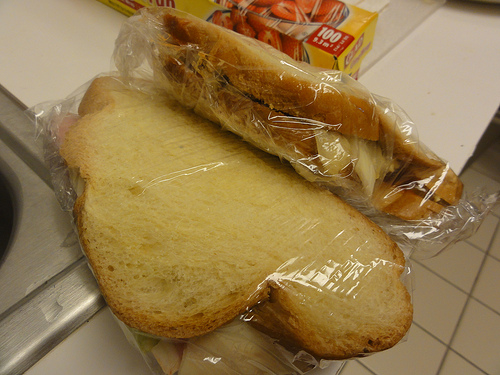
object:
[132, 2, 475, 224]
sandwich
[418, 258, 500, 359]
floor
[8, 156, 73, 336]
sink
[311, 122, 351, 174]
meat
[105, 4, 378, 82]
box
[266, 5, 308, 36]
plastic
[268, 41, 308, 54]
strawberries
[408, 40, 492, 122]
counter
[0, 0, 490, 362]
food prep area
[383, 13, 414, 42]
cutting board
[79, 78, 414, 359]
bread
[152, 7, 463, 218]
crust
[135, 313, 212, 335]
crust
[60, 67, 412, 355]
potatoe bread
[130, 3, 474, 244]
plastic bag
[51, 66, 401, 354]
plastic bag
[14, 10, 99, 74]
counter top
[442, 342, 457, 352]
grout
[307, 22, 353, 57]
label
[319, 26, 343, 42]
100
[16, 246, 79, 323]
stainless steel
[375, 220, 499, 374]
kitchen floor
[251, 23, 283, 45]
wrapped strawberries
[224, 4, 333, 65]
photo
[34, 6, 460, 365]
two wrapped sandwich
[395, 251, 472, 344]
square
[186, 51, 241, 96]
lettuce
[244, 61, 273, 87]
brown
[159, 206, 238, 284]
yellow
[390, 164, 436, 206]
sauce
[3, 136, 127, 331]
corner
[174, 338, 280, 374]
bag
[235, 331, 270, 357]
napkin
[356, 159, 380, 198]
cheese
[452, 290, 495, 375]
tile